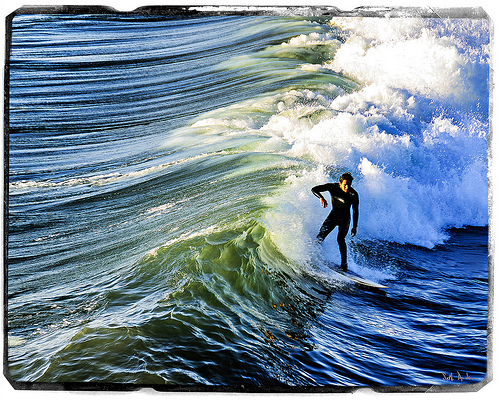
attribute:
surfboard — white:
[321, 254, 390, 291]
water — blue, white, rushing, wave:
[7, 14, 489, 384]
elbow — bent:
[311, 186, 319, 193]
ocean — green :
[9, 10, 494, 382]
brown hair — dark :
[332, 157, 362, 192]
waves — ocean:
[203, 90, 348, 381]